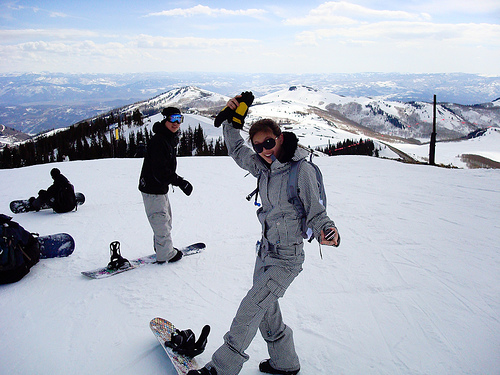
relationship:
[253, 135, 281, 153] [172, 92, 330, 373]
glasses of woman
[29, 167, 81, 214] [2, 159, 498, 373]
man sitting on snow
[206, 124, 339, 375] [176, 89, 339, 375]
ski suit of people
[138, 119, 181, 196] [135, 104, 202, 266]
black jacket of man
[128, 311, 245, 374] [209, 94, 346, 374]
snowboard of woman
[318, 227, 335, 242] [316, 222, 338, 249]
device in hand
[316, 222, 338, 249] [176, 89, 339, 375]
hand of people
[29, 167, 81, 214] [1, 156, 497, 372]
man sitting on ground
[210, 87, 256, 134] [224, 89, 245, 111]
glove in hand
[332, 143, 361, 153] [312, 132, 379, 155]
red line in trees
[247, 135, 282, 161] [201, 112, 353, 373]
glasses on woman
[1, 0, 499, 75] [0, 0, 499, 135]
clouds in sky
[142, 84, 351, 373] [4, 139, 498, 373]
people on a mountain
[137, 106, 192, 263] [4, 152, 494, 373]
man on a hill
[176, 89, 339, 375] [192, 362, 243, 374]
people has a foot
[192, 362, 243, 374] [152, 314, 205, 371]
foot on snowboard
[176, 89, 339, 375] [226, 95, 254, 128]
people holding an gloves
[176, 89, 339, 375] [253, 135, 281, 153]
people wearing glasses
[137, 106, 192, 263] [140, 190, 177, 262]
man wearing pants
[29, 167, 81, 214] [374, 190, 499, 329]
man sitting in snow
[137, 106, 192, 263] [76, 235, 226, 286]
man strapping on snow board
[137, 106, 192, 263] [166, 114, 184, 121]
man wearing goggles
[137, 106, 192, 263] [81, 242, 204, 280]
man standing on snowboard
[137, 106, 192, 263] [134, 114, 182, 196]
man wearing black jacket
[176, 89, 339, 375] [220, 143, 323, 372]
people wearing ski suit